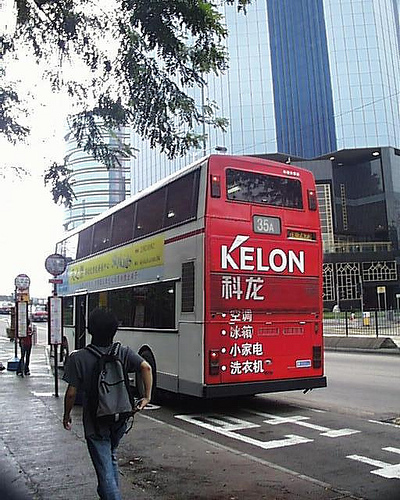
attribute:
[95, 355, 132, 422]
backpack — grey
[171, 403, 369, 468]
lines — painted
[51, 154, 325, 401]
bus — large, white, red, double decker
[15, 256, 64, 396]
stop — bus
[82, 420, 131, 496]
jeans — blue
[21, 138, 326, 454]
bus — large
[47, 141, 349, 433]
bus — large, red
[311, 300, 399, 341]
fence — black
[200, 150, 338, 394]
back — red , painted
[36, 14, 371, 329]
building — round, mirrored